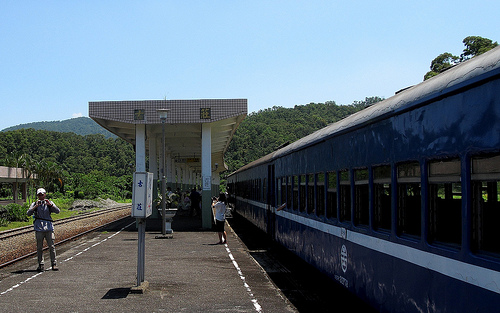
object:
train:
[223, 46, 498, 312]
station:
[0, 98, 300, 312]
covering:
[89, 100, 248, 170]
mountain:
[0, 116, 125, 139]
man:
[27, 187, 62, 272]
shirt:
[210, 199, 227, 221]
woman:
[210, 192, 229, 244]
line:
[220, 237, 265, 312]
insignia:
[339, 244, 349, 273]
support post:
[201, 123, 213, 231]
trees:
[113, 174, 134, 202]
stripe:
[224, 193, 500, 293]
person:
[186, 188, 204, 218]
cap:
[35, 187, 48, 195]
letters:
[137, 179, 145, 188]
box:
[130, 170, 155, 219]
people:
[165, 185, 173, 202]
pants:
[34, 224, 57, 264]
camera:
[36, 199, 48, 205]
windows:
[421, 155, 469, 261]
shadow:
[101, 285, 132, 299]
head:
[36, 187, 48, 200]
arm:
[44, 198, 62, 213]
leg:
[44, 232, 60, 271]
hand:
[44, 198, 52, 205]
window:
[366, 163, 396, 241]